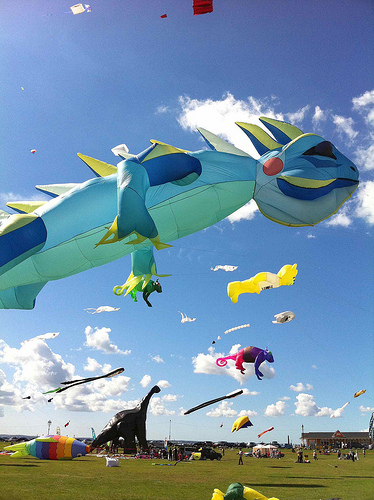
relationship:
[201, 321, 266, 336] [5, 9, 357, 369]
kite in sky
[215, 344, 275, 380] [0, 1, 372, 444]
kite in sky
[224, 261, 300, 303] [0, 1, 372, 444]
kite in sky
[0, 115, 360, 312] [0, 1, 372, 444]
dinosaur in sky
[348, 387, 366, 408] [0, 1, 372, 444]
kite in sky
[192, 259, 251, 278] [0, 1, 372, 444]
kite in sky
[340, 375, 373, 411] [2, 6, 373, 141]
kite in sky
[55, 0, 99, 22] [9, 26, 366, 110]
kite in sky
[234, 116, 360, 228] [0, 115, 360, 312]
dragon-head balloon of dinosaur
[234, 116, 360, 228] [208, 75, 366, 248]
dragon-head balloon of dragon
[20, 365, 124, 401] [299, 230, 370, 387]
kite on sky